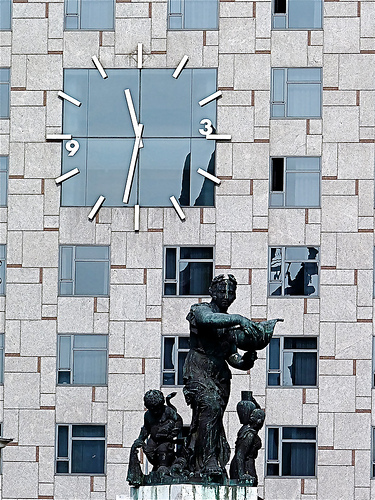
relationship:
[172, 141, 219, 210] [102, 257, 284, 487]
reflection of statue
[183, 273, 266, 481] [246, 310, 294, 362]
statue with bowl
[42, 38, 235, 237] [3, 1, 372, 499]
clock attached to hotel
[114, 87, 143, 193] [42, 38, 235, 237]
hands on clock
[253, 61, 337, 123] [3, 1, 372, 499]
window of hotel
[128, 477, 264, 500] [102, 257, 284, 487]
base of statue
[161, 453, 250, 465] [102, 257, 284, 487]
vase on statue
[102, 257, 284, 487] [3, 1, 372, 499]
statue beside hotel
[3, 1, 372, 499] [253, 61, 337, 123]
hotel has window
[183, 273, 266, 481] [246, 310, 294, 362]
statue holding bowl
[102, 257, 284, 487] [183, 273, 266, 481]
statue of statue